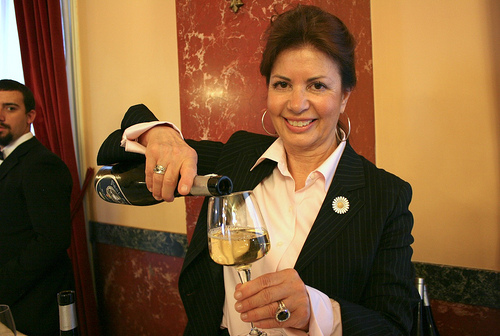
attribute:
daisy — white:
[332, 195, 351, 216]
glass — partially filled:
[205, 191, 271, 335]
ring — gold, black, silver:
[274, 301, 291, 322]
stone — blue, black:
[281, 312, 288, 318]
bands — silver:
[150, 165, 167, 177]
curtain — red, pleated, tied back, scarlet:
[12, 1, 120, 334]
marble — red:
[174, 1, 361, 305]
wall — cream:
[73, 0, 496, 273]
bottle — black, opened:
[96, 163, 232, 209]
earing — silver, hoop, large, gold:
[262, 108, 277, 143]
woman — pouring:
[102, 2, 427, 335]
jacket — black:
[100, 102, 424, 331]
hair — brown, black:
[259, 5, 358, 88]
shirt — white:
[119, 118, 348, 326]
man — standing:
[3, 79, 74, 333]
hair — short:
[1, 80, 37, 114]